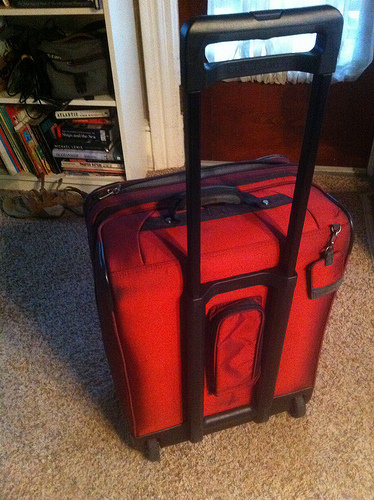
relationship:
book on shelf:
[57, 109, 108, 119] [1, 100, 124, 189]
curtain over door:
[207, 1, 372, 81] [178, 1, 369, 171]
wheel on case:
[287, 397, 306, 417] [81, 3, 350, 459]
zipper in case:
[322, 223, 343, 265] [81, 3, 350, 459]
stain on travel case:
[224, 314, 248, 382] [85, 7, 351, 462]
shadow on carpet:
[1, 211, 203, 405] [1, 196, 373, 499]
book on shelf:
[55, 109, 110, 119] [2, 103, 124, 196]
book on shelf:
[70, 117, 118, 127] [2, 103, 124, 196]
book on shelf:
[50, 122, 111, 146] [2, 103, 124, 196]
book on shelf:
[50, 119, 115, 141] [1, 100, 124, 189]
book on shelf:
[58, 156, 121, 176] [1, 100, 124, 189]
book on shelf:
[31, 113, 62, 171] [1, 101, 124, 173]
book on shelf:
[17, 120, 51, 179] [1, 100, 124, 189]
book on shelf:
[1, 107, 24, 175] [1, 101, 124, 181]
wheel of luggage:
[142, 441, 163, 464] [78, 5, 360, 464]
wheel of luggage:
[288, 395, 310, 421] [78, 5, 360, 464]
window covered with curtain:
[192, 0, 362, 95] [204, 1, 359, 83]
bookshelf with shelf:
[1, 1, 149, 194] [0, 173, 125, 190]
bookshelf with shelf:
[1, 1, 149, 194] [0, 93, 116, 107]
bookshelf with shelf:
[1, 1, 149, 194] [0, 6, 105, 16]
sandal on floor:
[0, 184, 85, 224] [1, 170, 362, 497]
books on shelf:
[0, 104, 123, 181] [0, 0, 150, 195]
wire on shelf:
[0, 48, 61, 119] [0, 93, 115, 109]